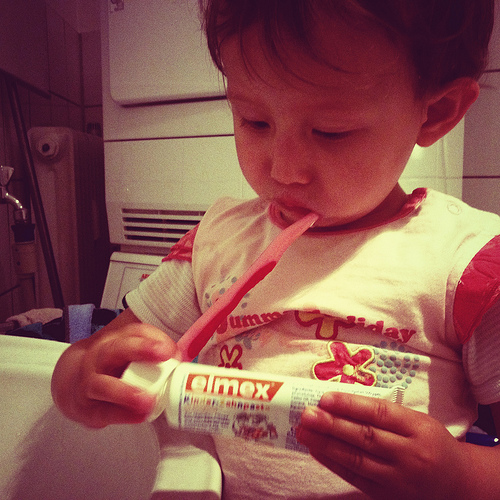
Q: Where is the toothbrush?
A: In the toddler's mouth.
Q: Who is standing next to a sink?
A: Toddler.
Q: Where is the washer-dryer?
A: Behind the toddler.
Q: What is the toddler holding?
A: Toothpaste.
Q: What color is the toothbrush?
A: Pink.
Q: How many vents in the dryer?
A: Four.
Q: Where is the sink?
A: Next to the toddler.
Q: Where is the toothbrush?
A: In the child's mouth.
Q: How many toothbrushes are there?
A: 1.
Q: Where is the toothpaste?
A: Child's hands.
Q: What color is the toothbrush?
A: Pink.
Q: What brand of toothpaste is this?
A: Eimex.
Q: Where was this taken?
A: Bathroom.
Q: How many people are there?
A: 1.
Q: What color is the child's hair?
A: Black.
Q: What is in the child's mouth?
A: Brush.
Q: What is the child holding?
A: Toothpaste.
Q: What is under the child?
A: Sink.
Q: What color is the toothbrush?
A: Pink.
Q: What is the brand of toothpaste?
A: Elmex.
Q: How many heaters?
A: One.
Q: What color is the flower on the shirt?
A: Pink.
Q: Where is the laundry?
A: Under washing machine.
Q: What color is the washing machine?
A: White.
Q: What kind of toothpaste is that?
A: Elmex.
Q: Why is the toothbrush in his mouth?
A: He's gonna brush his teeth.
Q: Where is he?
A: In the bathroom.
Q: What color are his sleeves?
A: Red and white.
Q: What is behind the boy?
A: A washer and dryer.